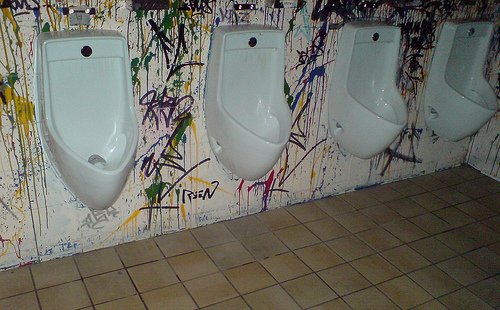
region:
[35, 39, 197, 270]
the toilet is white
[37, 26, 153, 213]
white bathroom urinal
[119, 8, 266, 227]
colorful graffiti on restroom wall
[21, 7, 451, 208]
vandalized bathroom walls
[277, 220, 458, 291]
beige tile floor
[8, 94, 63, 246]
yellow smearing paint on the wall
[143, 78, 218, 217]
black scribble on the wall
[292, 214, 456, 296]
square shapes on the floor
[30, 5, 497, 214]
four white urinals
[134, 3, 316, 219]
dirty wall in restroom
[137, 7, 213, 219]
green dripping paint on the wall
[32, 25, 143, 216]
a urinal on the wall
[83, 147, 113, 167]
a plastic pad in the urinal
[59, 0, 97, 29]
a metal sheet over the urinal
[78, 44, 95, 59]
a metal circle on the urinal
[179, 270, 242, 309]
a tile on the floor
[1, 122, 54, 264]
paint dripping down the wall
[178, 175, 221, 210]
black letters on the wall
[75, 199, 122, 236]
gray writing on the wall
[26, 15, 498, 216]
a row of urinals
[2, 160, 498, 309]
a tan tile floor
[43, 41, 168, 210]
toilet on the wall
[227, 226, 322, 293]
tile below the toilet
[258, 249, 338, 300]
square tile below the toilet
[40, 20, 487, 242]
four toilets on the wall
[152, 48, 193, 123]
paint on the wall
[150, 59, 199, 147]
different colors on the wall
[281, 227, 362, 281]
brown tile on the floor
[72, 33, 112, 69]
circle on the toilet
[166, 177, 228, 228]
word on the wall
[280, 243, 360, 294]
lines on the floor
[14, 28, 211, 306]
the toilet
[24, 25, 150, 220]
the toilet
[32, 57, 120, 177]
the toilet